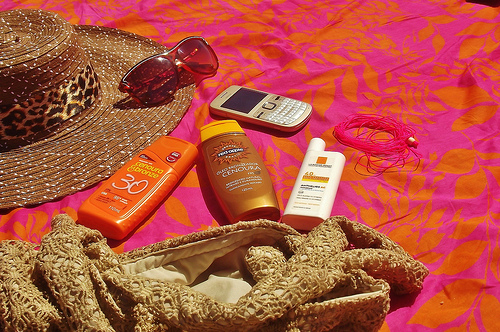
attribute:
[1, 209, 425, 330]
purse — empty, beige, crocheted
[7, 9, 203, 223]
hat — cheetah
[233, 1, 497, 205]
blanket — pink, orange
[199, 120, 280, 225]
bottle — brown, dark brown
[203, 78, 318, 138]
phone — black and brown, smart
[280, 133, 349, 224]
bottle care — white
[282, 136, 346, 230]
bottle — white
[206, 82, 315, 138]
cellphone — silver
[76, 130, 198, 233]
bottle — orange, sunblock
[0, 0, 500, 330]
towel — orange, pink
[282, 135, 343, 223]
bottle — white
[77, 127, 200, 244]
bottle — brown and yellow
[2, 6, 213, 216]
sun hat — brown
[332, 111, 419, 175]
bracelet — pink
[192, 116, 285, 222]
bottle — yellow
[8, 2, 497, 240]
towel — brown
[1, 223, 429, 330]
fabric — brown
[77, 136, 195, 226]
orange bottle — sunscreen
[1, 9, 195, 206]
sun hat — brown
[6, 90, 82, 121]
trim — leopard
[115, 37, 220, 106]
shades — sun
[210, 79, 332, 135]
phone — cell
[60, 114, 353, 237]
lotion — suntan 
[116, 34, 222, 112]
sunglasses — brown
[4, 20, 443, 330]
items — beach